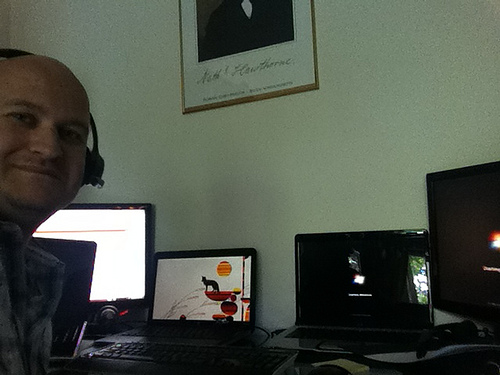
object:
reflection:
[405, 254, 430, 305]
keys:
[138, 340, 192, 360]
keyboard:
[73, 331, 299, 375]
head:
[0, 47, 105, 236]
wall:
[0, 0, 500, 334]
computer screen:
[31, 208, 146, 302]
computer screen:
[152, 256, 251, 322]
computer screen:
[300, 236, 431, 325]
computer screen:
[432, 168, 500, 301]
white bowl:
[423, 154, 494, 321]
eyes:
[58, 126, 83, 143]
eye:
[5, 111, 34, 125]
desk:
[47, 308, 500, 374]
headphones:
[0, 48, 106, 188]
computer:
[262, 229, 435, 354]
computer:
[425, 155, 500, 328]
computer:
[94, 247, 258, 347]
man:
[0, 40, 104, 375]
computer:
[24, 236, 97, 362]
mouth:
[11, 164, 62, 181]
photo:
[178, 0, 320, 114]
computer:
[32, 202, 156, 312]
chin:
[0, 180, 74, 213]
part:
[326, 197, 390, 221]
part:
[333, 98, 347, 148]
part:
[87, 22, 148, 100]